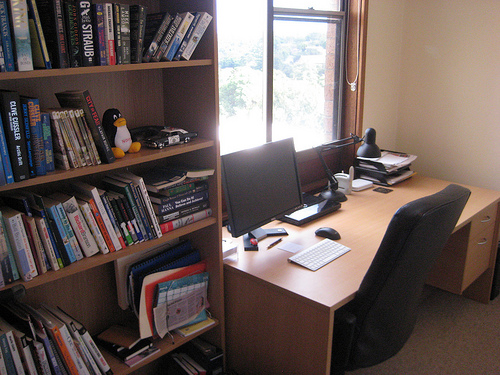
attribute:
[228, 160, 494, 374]
desk — brown, white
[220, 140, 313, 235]
monitor — black, off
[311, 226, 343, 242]
mouse — black, small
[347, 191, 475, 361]
chair — black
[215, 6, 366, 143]
window — white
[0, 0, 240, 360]
shelf — brown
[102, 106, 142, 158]
penguin — plush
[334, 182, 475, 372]
chair — black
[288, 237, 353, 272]
keyboard — white